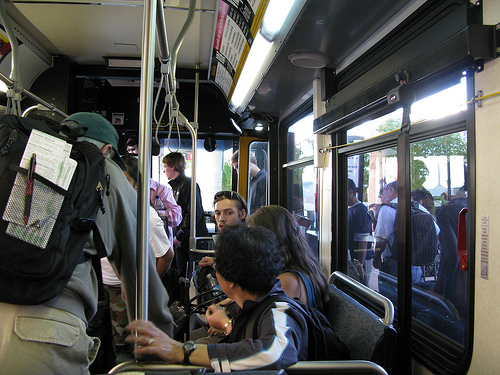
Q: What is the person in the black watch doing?
A: The person is sitting.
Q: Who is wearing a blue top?
A: A woman.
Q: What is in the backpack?
A: A pen and paper.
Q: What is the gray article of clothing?
A: A sweatshirt.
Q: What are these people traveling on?
A: A bus.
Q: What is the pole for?
A: To hold onto.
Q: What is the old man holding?
A: Backpack.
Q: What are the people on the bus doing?
A: Sitting.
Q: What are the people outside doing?
A: Waiting to get on.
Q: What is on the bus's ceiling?
A: Lights.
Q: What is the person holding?
A: Backpack.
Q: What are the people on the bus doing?
A: Riding.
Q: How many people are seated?
A: Three.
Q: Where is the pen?
A: Attached to the backpack worn by the man on the left.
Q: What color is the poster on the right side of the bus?
A: Black, white, and red.